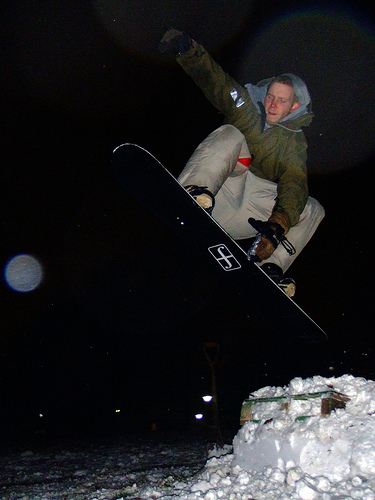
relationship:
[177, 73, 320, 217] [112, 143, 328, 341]
guy doing a trick on a snow board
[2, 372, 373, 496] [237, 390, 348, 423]
snow piled into ramp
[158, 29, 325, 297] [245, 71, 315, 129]
guy wearing hood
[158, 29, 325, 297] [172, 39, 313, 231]
guy wearing jacket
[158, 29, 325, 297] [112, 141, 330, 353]
guy riding snowboard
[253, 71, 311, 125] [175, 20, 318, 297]
head of person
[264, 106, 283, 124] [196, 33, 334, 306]
mouth of person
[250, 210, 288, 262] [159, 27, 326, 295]
hand of person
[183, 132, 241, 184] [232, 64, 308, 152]
leg of person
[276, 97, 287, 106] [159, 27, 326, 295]
eye of person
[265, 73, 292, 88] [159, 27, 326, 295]
hair of person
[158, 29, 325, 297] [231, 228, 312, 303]
guy has leg